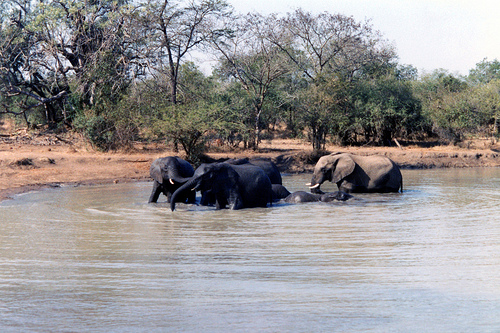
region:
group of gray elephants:
[132, 119, 414, 231]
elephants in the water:
[129, 131, 414, 242]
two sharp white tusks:
[304, 173, 325, 191]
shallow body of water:
[4, 170, 499, 332]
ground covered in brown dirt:
[0, 123, 496, 198]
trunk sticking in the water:
[162, 168, 206, 221]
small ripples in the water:
[79, 196, 387, 226]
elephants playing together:
[132, 151, 292, 210]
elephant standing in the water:
[300, 143, 425, 212]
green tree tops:
[412, 64, 496, 138]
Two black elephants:
[150, 154, 288, 208]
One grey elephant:
[307, 150, 403, 196]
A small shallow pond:
[4, 162, 496, 332]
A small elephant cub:
[284, 190, 355, 205]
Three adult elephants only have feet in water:
[147, 156, 402, 210]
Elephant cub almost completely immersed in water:
[285, 189, 353, 207]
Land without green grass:
[0, 142, 499, 176]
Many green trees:
[4, 3, 499, 147]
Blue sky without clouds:
[170, 2, 496, 75]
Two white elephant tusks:
[302, 180, 318, 187]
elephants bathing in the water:
[148, 146, 406, 206]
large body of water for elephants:
[2, 165, 497, 329]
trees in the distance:
[3, 2, 446, 147]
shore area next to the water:
[0, 148, 492, 196]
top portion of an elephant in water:
[307, 154, 402, 192]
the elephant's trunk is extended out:
[164, 159, 280, 206]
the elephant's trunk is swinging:
[146, 155, 194, 200]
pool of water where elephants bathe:
[1, 166, 499, 330]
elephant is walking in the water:
[304, 154, 404, 195]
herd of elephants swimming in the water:
[146, 140, 396, 210]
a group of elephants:
[43, 16, 453, 331]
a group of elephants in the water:
[119, 83, 461, 298]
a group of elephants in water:
[79, 91, 486, 326]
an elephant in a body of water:
[72, 71, 497, 273]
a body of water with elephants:
[12, 86, 484, 330]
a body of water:
[255, 221, 474, 330]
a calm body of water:
[233, 218, 418, 329]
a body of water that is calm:
[279, 211, 498, 326]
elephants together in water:
[69, 45, 471, 280]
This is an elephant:
[306, 141, 419, 202]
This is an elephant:
[269, 183, 364, 206]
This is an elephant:
[170, 167, 281, 215]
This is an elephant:
[141, 150, 196, 214]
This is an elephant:
[221, 151, 293, 180]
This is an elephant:
[259, 179, 294, 214]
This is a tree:
[155, 7, 192, 162]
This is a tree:
[221, 24, 270, 159]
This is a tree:
[298, 25, 351, 157]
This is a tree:
[66, 4, 125, 141]